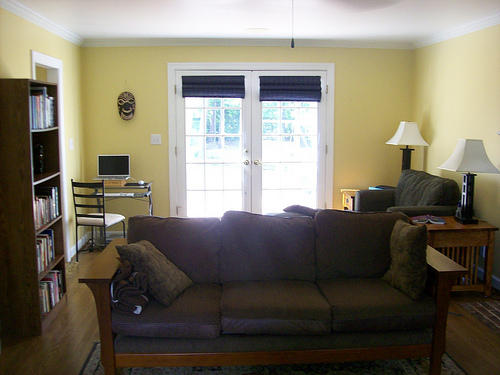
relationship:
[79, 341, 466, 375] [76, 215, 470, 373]
rug beneath couch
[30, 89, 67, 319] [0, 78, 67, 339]
books are sitting on bookshelf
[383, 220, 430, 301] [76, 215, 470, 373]
pillow sitting on couch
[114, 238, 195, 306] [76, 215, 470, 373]
pillow sitting on couch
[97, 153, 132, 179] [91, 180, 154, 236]
monitor sitting on top of desk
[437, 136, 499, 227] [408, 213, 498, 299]
lamp sitting on top of table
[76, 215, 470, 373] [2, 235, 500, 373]
couch sitting on floor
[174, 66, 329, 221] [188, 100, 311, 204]
doors are leading to outside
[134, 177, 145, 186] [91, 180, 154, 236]
mouse on desk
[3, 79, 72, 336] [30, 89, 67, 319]
bookshelf holding books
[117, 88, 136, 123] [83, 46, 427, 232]
mask decorating wall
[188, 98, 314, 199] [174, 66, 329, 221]
light coming through doors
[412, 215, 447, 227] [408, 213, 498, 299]
book sitting on table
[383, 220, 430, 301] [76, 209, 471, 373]
pillow on couch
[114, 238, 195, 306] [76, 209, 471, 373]
pillow on couch